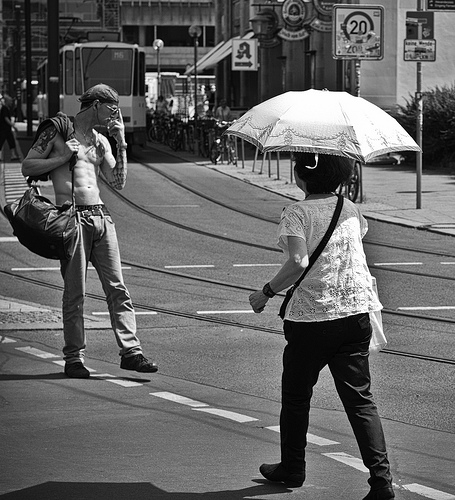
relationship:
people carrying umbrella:
[248, 143, 395, 500] [215, 77, 430, 187]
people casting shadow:
[3, 81, 160, 381] [1, 477, 293, 499]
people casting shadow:
[255, 153, 396, 498] [0, 371, 150, 384]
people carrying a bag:
[3, 81, 160, 381] [1, 109, 77, 262]